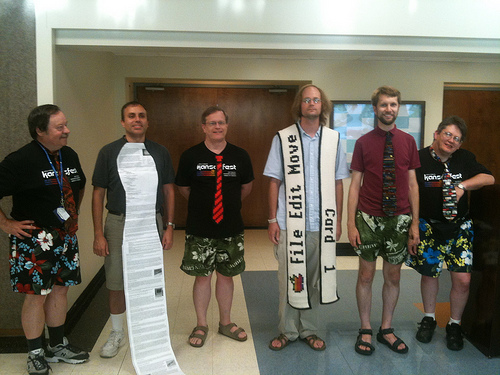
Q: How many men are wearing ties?
A: Four.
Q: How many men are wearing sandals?
A: Three.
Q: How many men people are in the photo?
A: Six.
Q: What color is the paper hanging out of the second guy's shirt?
A: White.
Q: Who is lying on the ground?
A: No one.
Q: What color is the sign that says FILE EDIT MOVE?
A: White.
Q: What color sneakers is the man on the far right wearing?
A: Black.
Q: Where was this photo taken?
A: In an office.